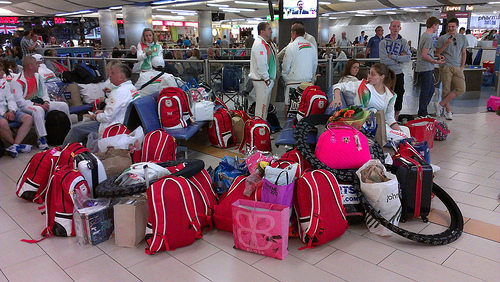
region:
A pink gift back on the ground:
[227, 195, 293, 266]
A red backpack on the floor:
[141, 169, 208, 256]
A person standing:
[246, 18, 278, 125]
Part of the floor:
[316, 257, 393, 274]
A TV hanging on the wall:
[276, 0, 321, 24]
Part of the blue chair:
[136, 100, 155, 110]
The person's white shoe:
[4, 143, 19, 155]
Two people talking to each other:
[413, 13, 471, 122]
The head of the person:
[105, 62, 135, 88]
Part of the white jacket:
[115, 90, 125, 98]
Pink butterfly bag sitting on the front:
[233, 200, 289, 261]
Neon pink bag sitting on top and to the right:
[311, 120, 372, 166]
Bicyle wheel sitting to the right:
[350, 171, 466, 247]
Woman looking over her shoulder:
[333, 60, 407, 131]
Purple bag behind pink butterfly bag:
[259, 176, 292, 201]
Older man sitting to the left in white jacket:
[67, 56, 136, 145]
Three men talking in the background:
[253, 18, 318, 91]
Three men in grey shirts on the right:
[376, 11, 470, 82]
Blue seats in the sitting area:
[132, 96, 198, 139]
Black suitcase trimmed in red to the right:
[395, 150, 432, 225]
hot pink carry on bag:
[310, 119, 374, 169]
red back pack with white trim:
[142, 178, 209, 251]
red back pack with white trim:
[296, 168, 349, 248]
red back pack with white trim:
[157, 80, 194, 130]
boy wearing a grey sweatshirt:
[375, 16, 412, 86]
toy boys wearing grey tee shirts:
[418, 11, 470, 117]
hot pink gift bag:
[230, 193, 294, 257]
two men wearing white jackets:
[250, 23, 318, 113]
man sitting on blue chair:
[87, 65, 142, 150]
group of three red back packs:
[19, 138, 107, 243]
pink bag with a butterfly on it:
[232, 197, 288, 258]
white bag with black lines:
[356, 157, 401, 233]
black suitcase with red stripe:
[388, 143, 430, 220]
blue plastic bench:
[135, 80, 207, 142]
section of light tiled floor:
[1, 113, 498, 278]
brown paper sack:
[114, 195, 146, 245]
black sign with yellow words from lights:
[442, 5, 486, 10]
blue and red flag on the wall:
[2, 23, 16, 33]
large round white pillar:
[123, 4, 153, 46]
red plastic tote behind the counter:
[482, 58, 494, 69]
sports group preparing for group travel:
[1, 14, 362, 261]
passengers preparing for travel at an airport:
[0, 19, 470, 117]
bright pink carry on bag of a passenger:
[316, 117, 370, 168]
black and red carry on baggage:
[391, 147, 434, 219]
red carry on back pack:
[146, 172, 203, 254]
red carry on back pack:
[274, 147, 311, 180]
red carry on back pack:
[291, 165, 346, 245]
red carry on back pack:
[155, 85, 186, 130]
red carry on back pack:
[295, 80, 327, 125]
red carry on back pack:
[16, 147, 56, 198]